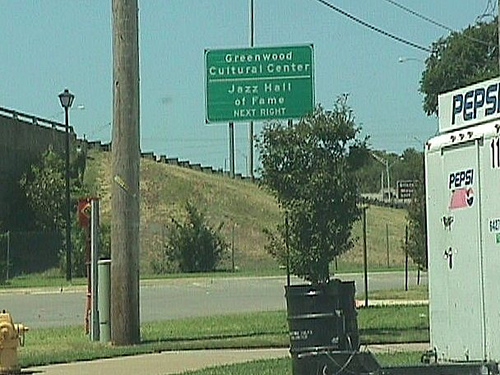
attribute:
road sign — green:
[178, 31, 351, 147]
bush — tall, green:
[161, 203, 228, 271]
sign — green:
[198, 43, 321, 125]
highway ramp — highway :
[141, 145, 293, 247]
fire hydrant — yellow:
[2, 309, 29, 374]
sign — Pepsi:
[447, 169, 476, 214]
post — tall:
[107, 2, 152, 347]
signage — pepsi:
[426, 81, 496, 125]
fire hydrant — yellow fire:
[0, 307, 30, 373]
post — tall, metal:
[66, 110, 72, 286]